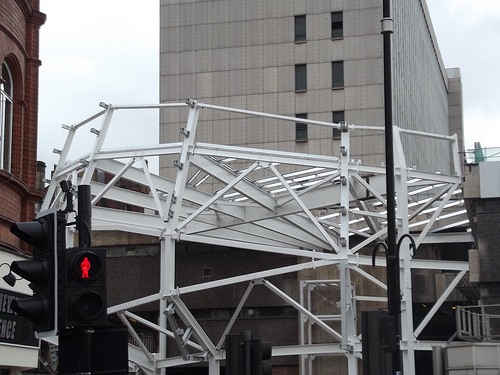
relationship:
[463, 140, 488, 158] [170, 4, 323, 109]
fence on building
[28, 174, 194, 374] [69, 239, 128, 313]
crosswalk has signal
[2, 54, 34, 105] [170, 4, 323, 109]
window on building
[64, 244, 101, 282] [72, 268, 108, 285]
person in red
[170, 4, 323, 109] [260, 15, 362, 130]
building has windows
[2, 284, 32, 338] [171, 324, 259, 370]
sign has letters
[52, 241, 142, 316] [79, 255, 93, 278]
light of person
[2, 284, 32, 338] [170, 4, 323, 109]
sign on building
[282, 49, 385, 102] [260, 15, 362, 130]
rows of windows